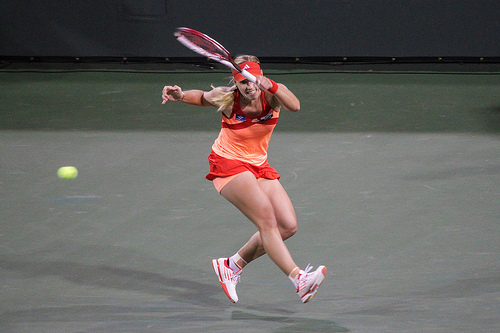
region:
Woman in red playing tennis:
[160, 21, 327, 309]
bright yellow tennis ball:
[55, 161, 76, 183]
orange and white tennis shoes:
[210, 253, 242, 304]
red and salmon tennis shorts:
[206, 153, 283, 195]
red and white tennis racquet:
[171, 22, 258, 80]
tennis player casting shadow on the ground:
[38, 250, 218, 307]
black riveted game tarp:
[337, 3, 493, 68]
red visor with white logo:
[228, 61, 263, 82]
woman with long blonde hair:
[206, 43, 265, 120]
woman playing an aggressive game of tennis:
[32, 8, 394, 325]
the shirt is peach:
[245, 133, 262, 158]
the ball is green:
[52, 159, 89, 191]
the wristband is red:
[263, 67, 281, 97]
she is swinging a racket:
[176, 19, 233, 71]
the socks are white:
[228, 244, 247, 274]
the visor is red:
[235, 58, 262, 84]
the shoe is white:
[293, 265, 331, 306]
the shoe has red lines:
[205, 248, 249, 311]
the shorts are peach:
[213, 178, 223, 192]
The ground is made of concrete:
[20, 206, 182, 311]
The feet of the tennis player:
[206, 255, 328, 310]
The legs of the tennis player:
[228, 168, 297, 267]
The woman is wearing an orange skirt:
[198, 145, 285, 190]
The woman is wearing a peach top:
[208, 92, 280, 169]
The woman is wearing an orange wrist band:
[265, 70, 281, 100]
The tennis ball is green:
[53, 152, 78, 187]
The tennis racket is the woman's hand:
[171, 23, 266, 92]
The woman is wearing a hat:
[226, 56, 269, 88]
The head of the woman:
[228, 50, 268, 103]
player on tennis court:
[148, 14, 355, 312]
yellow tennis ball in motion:
[34, 158, 95, 203]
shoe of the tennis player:
[285, 266, 351, 323]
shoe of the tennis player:
[206, 253, 243, 310]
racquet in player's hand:
[177, 26, 230, 69]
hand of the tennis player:
[153, 79, 181, 111]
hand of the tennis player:
[256, 75, 271, 95]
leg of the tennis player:
[233, 186, 293, 274]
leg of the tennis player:
[265, 183, 285, 226]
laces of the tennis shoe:
[304, 262, 317, 276]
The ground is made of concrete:
[361, 119, 461, 330]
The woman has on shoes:
[193, 250, 337, 307]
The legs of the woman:
[228, 169, 308, 270]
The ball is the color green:
[50, 160, 80, 183]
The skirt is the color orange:
[204, 143, 284, 187]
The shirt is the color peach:
[210, 89, 282, 165]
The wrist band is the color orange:
[265, 69, 281, 99]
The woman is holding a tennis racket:
[170, 9, 270, 99]